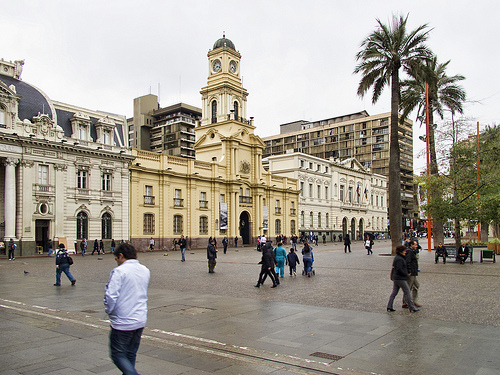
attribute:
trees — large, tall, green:
[355, 12, 470, 259]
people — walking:
[251, 237, 316, 292]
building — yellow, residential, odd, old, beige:
[128, 31, 302, 253]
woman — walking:
[302, 243, 315, 276]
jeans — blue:
[109, 327, 141, 373]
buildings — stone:
[1, 30, 415, 257]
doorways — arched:
[239, 209, 253, 245]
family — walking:
[275, 241, 317, 279]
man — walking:
[402, 240, 422, 310]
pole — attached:
[421, 79, 441, 249]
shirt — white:
[106, 260, 151, 333]